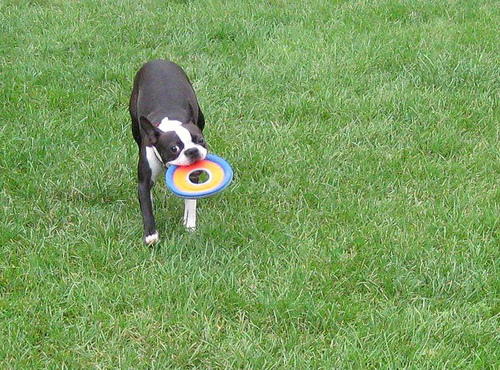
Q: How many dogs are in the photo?
A: One.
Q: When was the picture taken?
A: Daytime.